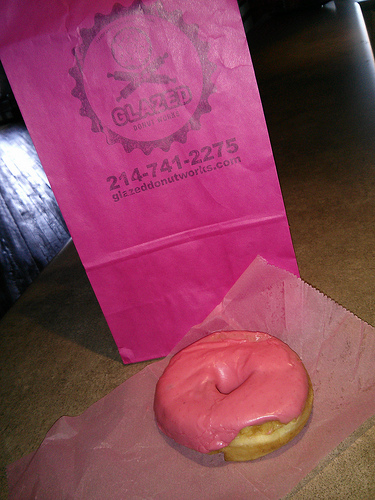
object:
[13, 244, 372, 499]
paper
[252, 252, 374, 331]
edge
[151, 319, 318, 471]
donut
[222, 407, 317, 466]
side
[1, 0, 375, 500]
table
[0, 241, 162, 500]
surface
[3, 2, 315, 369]
bag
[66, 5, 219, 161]
logo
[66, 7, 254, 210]
shop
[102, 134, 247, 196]
phone number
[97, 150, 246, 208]
website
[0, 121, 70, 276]
light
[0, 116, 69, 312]
wood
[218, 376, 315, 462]
icing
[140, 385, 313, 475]
outline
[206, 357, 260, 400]
hole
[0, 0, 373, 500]
countertop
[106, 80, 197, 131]
glazed